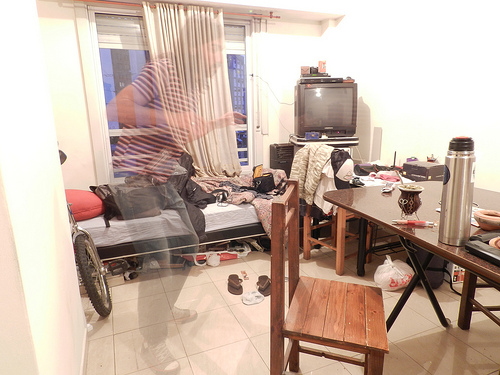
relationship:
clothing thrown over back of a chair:
[293, 147, 343, 210] [264, 181, 404, 369]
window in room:
[95, 9, 256, 180] [10, 5, 475, 363]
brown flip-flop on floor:
[226, 274, 245, 299] [105, 240, 462, 368]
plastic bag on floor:
[371, 254, 416, 295] [119, 230, 447, 369]